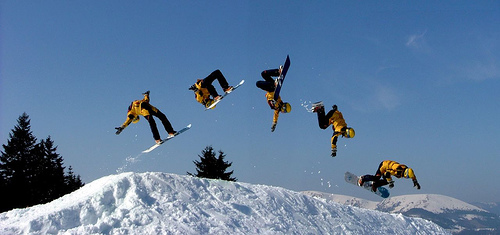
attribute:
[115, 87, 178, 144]
person — preparing to flip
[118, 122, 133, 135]
arm — spread out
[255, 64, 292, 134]
person — upside down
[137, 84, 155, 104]
arm — spread out